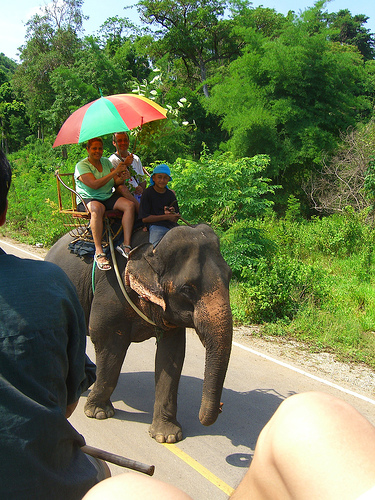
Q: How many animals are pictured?
A: One.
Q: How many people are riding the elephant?
A: Three.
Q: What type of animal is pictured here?
A: Elephant.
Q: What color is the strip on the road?
A: Yellow.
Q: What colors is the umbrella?
A: Green, red and yellow.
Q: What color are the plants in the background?
A: Green.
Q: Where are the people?
A: Under umbrella.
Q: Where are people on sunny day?
A: Under umbrella.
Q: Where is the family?
A: Sitting on elephant.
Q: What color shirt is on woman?
A: Green.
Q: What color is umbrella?
A: Red green and yellow.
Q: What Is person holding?
A: An umbrella.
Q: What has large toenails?
A: Front legs of elephant.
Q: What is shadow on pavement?
A: Elephant.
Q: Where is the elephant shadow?
A: On pavement.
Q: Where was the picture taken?
A: On a street.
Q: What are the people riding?
A: Elephant.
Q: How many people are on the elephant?
A: 3.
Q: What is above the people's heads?
A: Umbrella.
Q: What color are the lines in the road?
A: Yellow.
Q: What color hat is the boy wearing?
A: Blue.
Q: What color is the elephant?
A: Gray.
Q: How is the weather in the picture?
A: Sunny.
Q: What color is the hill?
A: Green.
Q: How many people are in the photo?
A: Four.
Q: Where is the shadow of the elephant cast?
A: On road.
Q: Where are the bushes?
A: Side of road.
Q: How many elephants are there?
A: One.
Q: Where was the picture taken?
A: India.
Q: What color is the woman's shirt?
A: Green.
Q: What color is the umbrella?
A: Green and red.